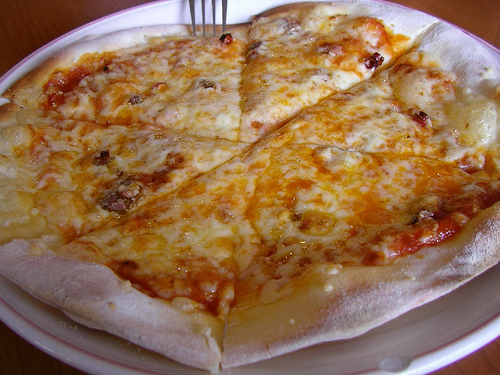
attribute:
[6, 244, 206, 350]
crust — white, thin, dusted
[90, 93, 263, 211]
cheese — burned, melted, yellow, white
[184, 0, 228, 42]
fork — ready, metal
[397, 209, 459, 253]
sauce — red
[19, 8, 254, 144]
slice — large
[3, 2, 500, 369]
pizza — greasy, cooked, round, sliced, cut, chipped, portioned, white, topped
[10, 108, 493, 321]
half — cut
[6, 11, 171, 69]
border — pink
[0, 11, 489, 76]
table — wooden